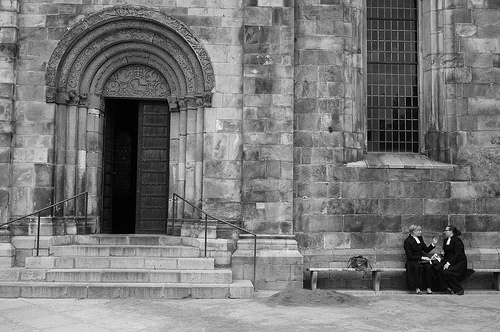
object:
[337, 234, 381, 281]
bird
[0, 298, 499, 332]
road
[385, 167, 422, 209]
ground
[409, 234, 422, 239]
collar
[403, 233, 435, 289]
dress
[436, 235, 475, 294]
dress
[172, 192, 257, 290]
metal rail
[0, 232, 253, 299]
stairs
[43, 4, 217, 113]
arch way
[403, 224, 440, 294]
lady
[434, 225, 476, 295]
lady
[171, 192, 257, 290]
railing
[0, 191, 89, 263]
railing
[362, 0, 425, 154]
window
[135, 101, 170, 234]
door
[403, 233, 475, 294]
costumes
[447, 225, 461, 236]
hair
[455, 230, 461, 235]
ponytail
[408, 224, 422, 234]
hair cut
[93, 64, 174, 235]
door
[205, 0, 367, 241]
wall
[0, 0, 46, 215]
wall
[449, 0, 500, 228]
wall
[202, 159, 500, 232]
wall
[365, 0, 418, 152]
bars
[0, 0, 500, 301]
building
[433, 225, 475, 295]
sitting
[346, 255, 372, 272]
bag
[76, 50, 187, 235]
door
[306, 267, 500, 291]
bench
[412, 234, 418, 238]
neck